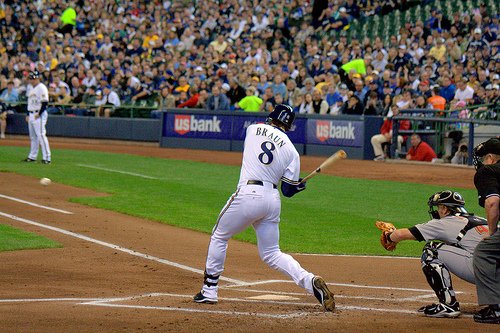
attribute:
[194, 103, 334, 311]
player — 8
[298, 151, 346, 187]
bat — wood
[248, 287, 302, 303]
base — home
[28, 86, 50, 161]
uniform — white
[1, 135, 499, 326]
field — grassy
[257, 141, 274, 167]
number — 8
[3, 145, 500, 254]
grass — green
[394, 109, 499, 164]
raling — steel